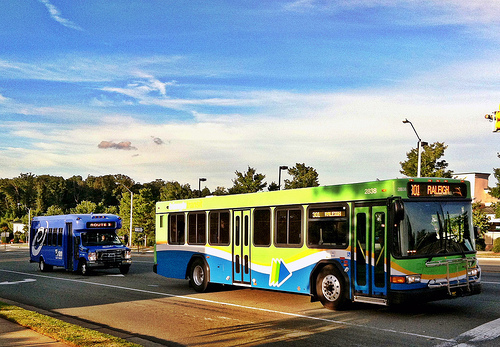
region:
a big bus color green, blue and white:
[145, 172, 484, 315]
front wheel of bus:
[305, 257, 357, 317]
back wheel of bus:
[179, 251, 214, 296]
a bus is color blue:
[21, 202, 136, 282]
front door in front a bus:
[343, 194, 395, 304]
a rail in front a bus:
[422, 251, 484, 298]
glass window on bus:
[388, 197, 478, 255]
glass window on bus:
[374, 212, 386, 289]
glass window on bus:
[355, 211, 365, 287]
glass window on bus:
[309, 220, 345, 245]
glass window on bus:
[288, 205, 300, 246]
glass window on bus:
[275, 206, 287, 242]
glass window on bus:
[251, 208, 273, 243]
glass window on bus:
[208, 210, 227, 240]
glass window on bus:
[187, 213, 206, 244]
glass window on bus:
[167, 210, 185, 242]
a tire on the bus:
[311, 266, 351, 312]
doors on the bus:
[347, 227, 389, 286]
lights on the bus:
[393, 265, 421, 289]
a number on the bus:
[354, 184, 382, 198]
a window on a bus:
[182, 214, 216, 244]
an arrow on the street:
[5, 267, 34, 295]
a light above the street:
[273, 156, 294, 184]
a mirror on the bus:
[116, 225, 138, 249]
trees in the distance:
[85, 174, 152, 217]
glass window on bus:
[400, 203, 475, 253]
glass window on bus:
[354, 210, 364, 287]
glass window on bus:
[218, 211, 228, 242]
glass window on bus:
[209, 211, 216, 243]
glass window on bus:
[196, 210, 206, 243]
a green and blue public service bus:
[152, 176, 481, 310]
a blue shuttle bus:
[29, 212, 131, 276]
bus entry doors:
[351, 206, 388, 298]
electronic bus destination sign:
[410, 180, 465, 197]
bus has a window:
[176, 211, 186, 242]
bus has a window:
[188, 209, 196, 243]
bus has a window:
[198, 209, 206, 244]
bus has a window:
[208, 212, 218, 245]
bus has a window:
[219, 208, 228, 243]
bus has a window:
[253, 205, 268, 244]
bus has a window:
[278, 208, 288, 245]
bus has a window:
[288, 208, 300, 242]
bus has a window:
[399, 200, 445, 255]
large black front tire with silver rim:
[313, 259, 350, 310]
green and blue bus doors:
[350, 205, 390, 301]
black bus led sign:
[407, 180, 467, 199]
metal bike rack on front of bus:
[422, 257, 479, 297]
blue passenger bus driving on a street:
[27, 210, 132, 277]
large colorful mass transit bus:
[152, 176, 484, 310]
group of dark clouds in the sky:
[96, 132, 173, 159]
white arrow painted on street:
[0, 273, 36, 288]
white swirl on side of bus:
[30, 216, 50, 260]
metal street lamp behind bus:
[395, 113, 454, 178]